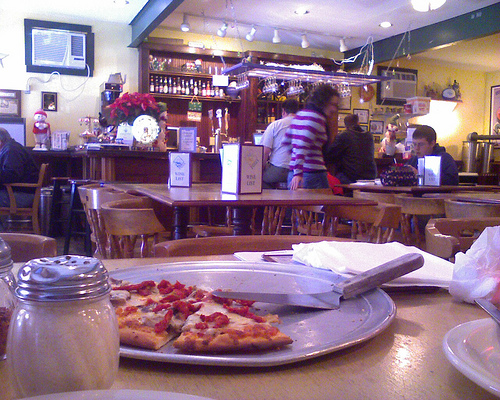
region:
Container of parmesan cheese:
[13, 247, 122, 398]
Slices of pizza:
[106, 260, 298, 370]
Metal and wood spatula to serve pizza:
[210, 249, 434, 316]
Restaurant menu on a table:
[214, 137, 269, 199]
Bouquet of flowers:
[107, 83, 163, 145]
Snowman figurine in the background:
[27, 106, 58, 151]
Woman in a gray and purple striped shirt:
[272, 86, 345, 198]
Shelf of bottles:
[146, 71, 242, 99]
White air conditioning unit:
[25, 22, 107, 77]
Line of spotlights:
[175, 14, 366, 58]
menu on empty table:
[168, 149, 190, 186]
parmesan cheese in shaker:
[4, 254, 119, 398]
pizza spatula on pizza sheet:
[208, 243, 428, 318]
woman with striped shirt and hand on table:
[282, 80, 341, 195]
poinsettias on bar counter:
[105, 87, 157, 149]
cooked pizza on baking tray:
[170, 296, 292, 356]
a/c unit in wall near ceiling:
[22, 13, 94, 75]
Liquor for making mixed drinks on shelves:
[145, 69, 216, 98]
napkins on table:
[291, 239, 468, 289]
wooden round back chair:
[98, 191, 163, 256]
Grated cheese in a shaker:
[4, 254, 121, 393]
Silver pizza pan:
[94, 257, 396, 368]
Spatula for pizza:
[208, 252, 431, 310]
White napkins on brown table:
[291, 235, 458, 297]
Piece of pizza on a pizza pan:
[176, 288, 290, 348]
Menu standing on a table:
[221, 139, 265, 196]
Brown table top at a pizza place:
[123, 177, 379, 207]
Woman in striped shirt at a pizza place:
[276, 80, 343, 187]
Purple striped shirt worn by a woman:
[281, 112, 330, 173]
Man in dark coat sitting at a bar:
[333, 111, 376, 184]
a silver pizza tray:
[94, 231, 424, 358]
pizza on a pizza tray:
[83, 255, 305, 367]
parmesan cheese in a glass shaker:
[0, 242, 145, 399]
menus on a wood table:
[157, 132, 359, 224]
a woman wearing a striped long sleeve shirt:
[284, 82, 366, 205]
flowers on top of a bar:
[97, 89, 219, 171]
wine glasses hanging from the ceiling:
[211, 53, 413, 102]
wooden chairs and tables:
[62, 156, 432, 261]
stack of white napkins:
[283, 225, 498, 330]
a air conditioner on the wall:
[20, 21, 130, 97]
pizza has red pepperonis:
[161, 267, 328, 397]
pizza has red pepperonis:
[176, 285, 283, 380]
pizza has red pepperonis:
[88, 247, 283, 380]